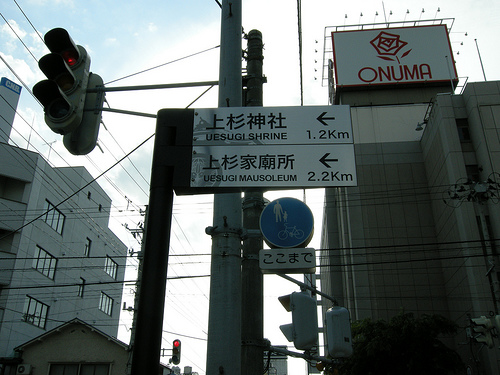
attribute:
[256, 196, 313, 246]
sign — blue , white 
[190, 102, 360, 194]
sign — black, white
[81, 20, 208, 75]
sky — blue, clear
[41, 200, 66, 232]
window — glass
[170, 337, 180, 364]
light — stop light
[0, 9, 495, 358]
sky — blue 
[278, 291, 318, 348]
sign — walking sign, electronic, white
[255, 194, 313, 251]
sign — round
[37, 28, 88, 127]
traffic light — red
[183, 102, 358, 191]
street sign — black, white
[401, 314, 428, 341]
leaves — green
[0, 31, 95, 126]
stop light — electronic, black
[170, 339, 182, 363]
light — traffic light, red, glowing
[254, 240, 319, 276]
sign — white